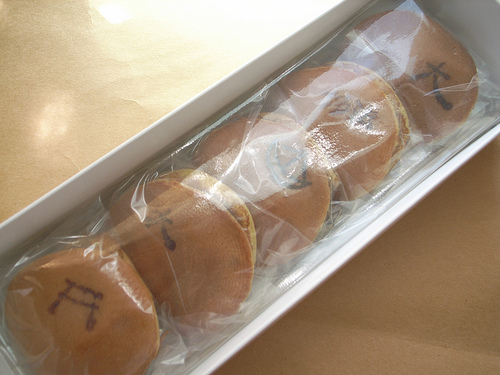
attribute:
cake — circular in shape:
[6, 237, 164, 371]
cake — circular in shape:
[115, 161, 257, 319]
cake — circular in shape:
[201, 108, 331, 256]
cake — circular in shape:
[279, 57, 416, 197]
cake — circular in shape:
[354, 5, 481, 147]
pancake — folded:
[3, 3, 488, 374]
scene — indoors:
[1, 35, 498, 373]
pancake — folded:
[335, 8, 478, 144]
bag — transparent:
[0, 0, 498, 373]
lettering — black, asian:
[46, 275, 103, 331]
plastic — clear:
[1, 194, 188, 373]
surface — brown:
[361, 252, 498, 374]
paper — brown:
[0, 5, 305, 192]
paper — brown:
[255, 141, 494, 371]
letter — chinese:
[145, 202, 185, 256]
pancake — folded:
[107, 177, 258, 318]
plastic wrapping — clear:
[290, 9, 451, 209]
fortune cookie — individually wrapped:
[362, 19, 487, 138]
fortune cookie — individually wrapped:
[287, 59, 417, 206]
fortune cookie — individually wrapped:
[203, 112, 345, 236]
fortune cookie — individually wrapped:
[117, 176, 257, 328]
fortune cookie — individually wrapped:
[14, 226, 163, 373]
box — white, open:
[0, 6, 492, 371]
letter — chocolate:
[44, 274, 106, 332]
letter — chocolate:
[134, 203, 182, 260]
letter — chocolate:
[256, 139, 319, 200]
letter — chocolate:
[326, 86, 380, 134]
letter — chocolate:
[410, 48, 457, 110]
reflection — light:
[85, 1, 334, 112]